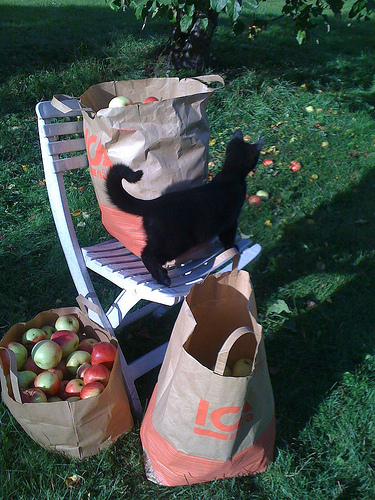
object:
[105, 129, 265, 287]
cat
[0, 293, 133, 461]
sack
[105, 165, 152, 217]
tail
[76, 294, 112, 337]
handle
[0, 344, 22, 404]
handle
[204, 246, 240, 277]
handle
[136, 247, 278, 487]
sack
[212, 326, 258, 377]
handle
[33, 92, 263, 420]
chair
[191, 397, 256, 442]
writing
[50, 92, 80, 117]
handle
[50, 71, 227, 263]
sack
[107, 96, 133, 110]
apples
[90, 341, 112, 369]
apple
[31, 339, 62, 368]
apple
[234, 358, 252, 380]
apples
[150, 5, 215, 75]
trunk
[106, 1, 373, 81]
tree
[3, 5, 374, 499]
grass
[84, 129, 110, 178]
logo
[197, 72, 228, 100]
handle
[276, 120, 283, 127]
leaves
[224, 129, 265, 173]
head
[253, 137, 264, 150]
ear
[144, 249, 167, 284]
leg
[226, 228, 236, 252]
leg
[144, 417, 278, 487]
stripe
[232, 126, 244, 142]
ear